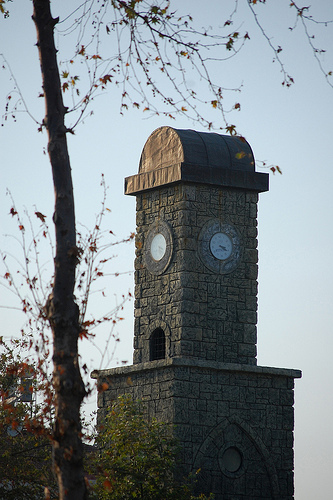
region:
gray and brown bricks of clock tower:
[155, 138, 234, 168]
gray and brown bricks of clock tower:
[150, 195, 197, 214]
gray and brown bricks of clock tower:
[183, 192, 238, 215]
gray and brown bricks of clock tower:
[190, 278, 244, 323]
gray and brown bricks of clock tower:
[185, 313, 244, 350]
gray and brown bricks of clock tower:
[142, 285, 174, 313]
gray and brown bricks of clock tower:
[148, 375, 228, 411]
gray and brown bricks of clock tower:
[197, 373, 276, 409]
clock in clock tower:
[145, 222, 174, 269]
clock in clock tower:
[198, 221, 254, 269]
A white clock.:
[207, 230, 234, 263]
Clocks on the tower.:
[135, 214, 251, 287]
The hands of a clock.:
[217, 239, 227, 253]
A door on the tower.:
[141, 320, 170, 365]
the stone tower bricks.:
[179, 270, 256, 365]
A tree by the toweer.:
[98, 392, 213, 498]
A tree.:
[26, 4, 108, 498]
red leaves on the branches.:
[0, 188, 58, 462]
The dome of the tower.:
[116, 114, 278, 199]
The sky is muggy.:
[301, 301, 331, 498]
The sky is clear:
[214, 9, 305, 91]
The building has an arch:
[184, 397, 287, 494]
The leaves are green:
[79, 393, 176, 485]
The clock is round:
[198, 213, 237, 294]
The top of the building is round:
[124, 109, 267, 204]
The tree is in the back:
[14, 421, 70, 499]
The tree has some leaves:
[14, 4, 242, 153]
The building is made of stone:
[159, 383, 266, 481]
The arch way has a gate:
[133, 312, 188, 372]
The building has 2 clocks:
[123, 202, 245, 282]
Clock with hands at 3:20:
[200, 227, 241, 268]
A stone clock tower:
[131, 140, 273, 491]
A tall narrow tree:
[26, 4, 99, 482]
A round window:
[207, 440, 260, 481]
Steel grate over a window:
[139, 316, 175, 365]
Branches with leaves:
[109, 9, 197, 79]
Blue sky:
[300, 398, 327, 436]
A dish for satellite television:
[2, 416, 30, 438]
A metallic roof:
[112, 126, 278, 197]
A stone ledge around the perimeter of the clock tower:
[88, 358, 319, 375]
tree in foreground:
[0, 83, 119, 459]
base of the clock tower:
[90, 357, 313, 498]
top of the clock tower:
[117, 122, 267, 370]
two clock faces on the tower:
[130, 217, 248, 274]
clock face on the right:
[196, 219, 246, 274]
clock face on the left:
[133, 217, 180, 280]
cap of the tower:
[119, 123, 274, 197]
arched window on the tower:
[136, 316, 177, 366]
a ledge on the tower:
[80, 350, 310, 389]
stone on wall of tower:
[140, 285, 180, 322]